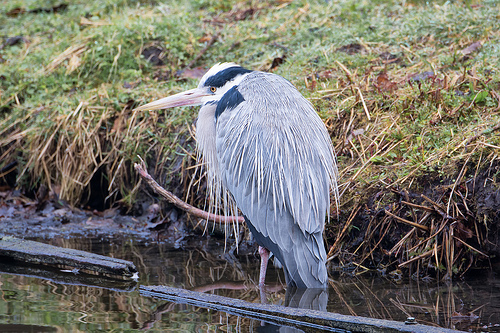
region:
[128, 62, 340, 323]
bird standing in the water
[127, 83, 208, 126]
beak of a bird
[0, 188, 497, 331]
water near some grass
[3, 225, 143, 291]
stick lying in the water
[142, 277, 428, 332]
stick lying in the water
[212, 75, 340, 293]
grey wing of a bird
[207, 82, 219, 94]
yellow eye of a bird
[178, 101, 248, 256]
white chest feathers of a bird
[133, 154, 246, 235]
stick near a bird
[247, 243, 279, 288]
leg of a bird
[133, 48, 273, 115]
Black and white feathers on head.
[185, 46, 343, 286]
Gray feathers on body of bird.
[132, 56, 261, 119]
Long tan beak on bird.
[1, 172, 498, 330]
Water beside grass and dirt.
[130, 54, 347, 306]
Bird standing in water.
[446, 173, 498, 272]
Mud beside the water.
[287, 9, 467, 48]
Green grass on the land.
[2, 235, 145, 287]
Wood in the water.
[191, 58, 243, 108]
Yellow eye on the bird.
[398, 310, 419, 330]
Bolt on the piece of wood.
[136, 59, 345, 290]
bird standing in water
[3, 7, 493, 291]
green grass on water bank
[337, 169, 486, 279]
dried grass on mud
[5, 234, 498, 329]
surface of calm water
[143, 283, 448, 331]
top of board in water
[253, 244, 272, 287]
pink leg of bird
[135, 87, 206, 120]
long pointed bird beak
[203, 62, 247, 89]
black stripe on white head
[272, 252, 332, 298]
tail feathers in water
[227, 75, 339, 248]
feathers on bird back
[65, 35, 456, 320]
A bird is by the side of a river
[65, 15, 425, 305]
A bird has landed in a lake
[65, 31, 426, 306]
The bird is looking for food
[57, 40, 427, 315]
The bird is looking for its prey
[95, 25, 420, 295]
The bird wants to find some dinner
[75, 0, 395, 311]
The bird has a long beak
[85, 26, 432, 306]
The bird has colorful feathers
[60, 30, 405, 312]
The bird is looking for its mate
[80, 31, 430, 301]
The bird is hiding from predators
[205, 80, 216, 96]
The eye of a bird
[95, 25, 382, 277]
bird next to water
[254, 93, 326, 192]
feathers on the bird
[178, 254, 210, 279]
water next to bird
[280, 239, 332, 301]
tail feathers of the bird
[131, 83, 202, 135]
beak of the bird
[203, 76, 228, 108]
eye of the bird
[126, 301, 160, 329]
reflection in the water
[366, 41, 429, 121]
land next to bird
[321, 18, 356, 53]
green grass on the ground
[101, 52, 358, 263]
bird with a long beak